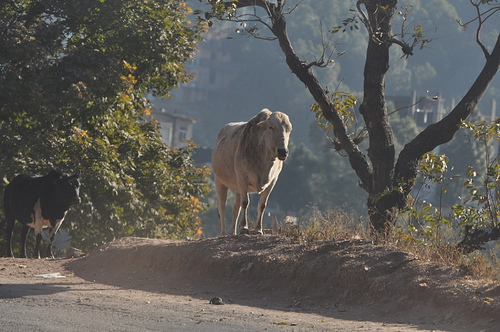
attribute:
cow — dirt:
[211, 108, 296, 233]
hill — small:
[78, 230, 495, 327]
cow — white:
[213, 106, 288, 241]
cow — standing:
[206, 105, 298, 229]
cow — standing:
[6, 156, 86, 256]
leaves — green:
[3, 101, 205, 253]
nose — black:
[277, 147, 288, 159]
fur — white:
[202, 140, 264, 182]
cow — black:
[3, 165, 83, 260]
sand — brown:
[0, 254, 451, 330]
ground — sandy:
[0, 231, 482, 326]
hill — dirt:
[59, 226, 499, 330]